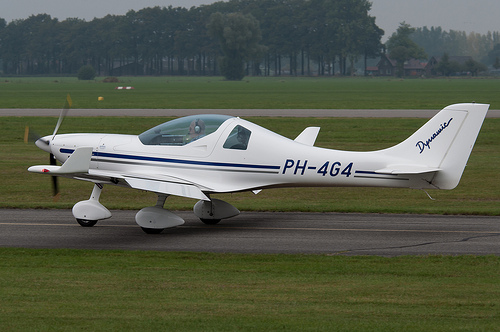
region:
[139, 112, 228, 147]
cockpit of the plane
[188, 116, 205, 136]
pilot of the plane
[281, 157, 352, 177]
identification number on plane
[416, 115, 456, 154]
the text is black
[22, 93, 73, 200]
the propeller is spinning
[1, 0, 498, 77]
lots of trees in distance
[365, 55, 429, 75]
cabin in the distance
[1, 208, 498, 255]
the runway is gray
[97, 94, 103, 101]
yellow object on ground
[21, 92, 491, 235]
A plane on a runway.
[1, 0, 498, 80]
Trees by an airport.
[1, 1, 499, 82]
Trees in the distance.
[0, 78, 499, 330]
Grass at an airport.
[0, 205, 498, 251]
A planes runway.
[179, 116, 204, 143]
The pilot in a plane.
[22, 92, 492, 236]
A plane taking off.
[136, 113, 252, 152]
Windows on a plane.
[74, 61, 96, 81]
A bush on the grass.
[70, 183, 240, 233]
A planes landing gear.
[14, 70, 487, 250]
the plane is white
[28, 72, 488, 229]
the plane is white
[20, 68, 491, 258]
the plane is white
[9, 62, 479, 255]
the plane is white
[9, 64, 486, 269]
the plane is white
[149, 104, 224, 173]
a pilot in the plane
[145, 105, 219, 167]
a pilot in the plane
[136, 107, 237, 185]
a pilot in the plane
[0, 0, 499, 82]
Trees by the runway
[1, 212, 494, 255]
The runway beneath the airplane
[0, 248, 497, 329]
Grass next to the runway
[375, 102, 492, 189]
The tail of the airplane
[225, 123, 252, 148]
A window on the airplane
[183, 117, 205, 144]
The pilot flying hte airplane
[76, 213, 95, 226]
A wheel on the airplane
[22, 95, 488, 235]
An airplane on the runway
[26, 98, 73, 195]
The propeller of the airplane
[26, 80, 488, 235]
a plane for 2 passengers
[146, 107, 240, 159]
canopy of a plane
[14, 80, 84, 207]
rotors of a small plane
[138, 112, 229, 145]
glass cockpit on the plane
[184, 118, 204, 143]
the pilot in the cockpit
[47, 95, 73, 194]
propeller on the front of the plane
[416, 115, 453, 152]
name on the tail of the remain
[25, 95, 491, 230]
a white, small plane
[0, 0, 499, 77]
thick, green trees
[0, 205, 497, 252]
concrete runway for the plane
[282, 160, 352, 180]
PH-4G4 on the side of the plane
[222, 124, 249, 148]
a small window on the plane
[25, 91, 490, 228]
a plane on the runway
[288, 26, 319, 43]
green leaves on the tree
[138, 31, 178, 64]
green leaves on the tree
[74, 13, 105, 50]
green leaves on the tree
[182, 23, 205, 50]
green leaves on the tree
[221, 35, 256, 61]
green leaves on the tree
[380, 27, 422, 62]
green leaves on the tree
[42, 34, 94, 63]
green leaves on the tree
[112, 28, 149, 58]
green leaves on the tree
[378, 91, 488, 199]
The tail of a small airplane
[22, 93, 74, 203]
The propeller of an airplane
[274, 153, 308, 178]
The letters 'p' and 'h'